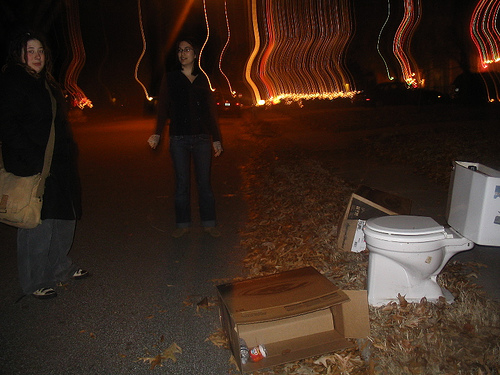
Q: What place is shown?
A: It is a roadside.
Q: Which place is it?
A: It is a roadside.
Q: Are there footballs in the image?
A: No, there are no footballs.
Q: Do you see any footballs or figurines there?
A: No, there are no footballs or figurines.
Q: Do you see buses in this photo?
A: No, there are no buses.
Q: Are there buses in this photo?
A: No, there are no buses.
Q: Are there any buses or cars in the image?
A: No, there are no buses or cars.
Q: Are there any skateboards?
A: No, there are no skateboards.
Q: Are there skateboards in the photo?
A: No, there are no skateboards.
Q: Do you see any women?
A: Yes, there is a woman.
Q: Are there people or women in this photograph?
A: Yes, there is a woman.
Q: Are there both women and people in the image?
A: Yes, there are both a woman and a person.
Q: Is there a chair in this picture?
A: No, there are no chairs.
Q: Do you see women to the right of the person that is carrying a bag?
A: Yes, there is a woman to the right of the person.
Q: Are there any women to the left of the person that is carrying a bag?
A: No, the woman is to the right of the person.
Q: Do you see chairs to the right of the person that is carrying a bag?
A: No, there is a woman to the right of the person.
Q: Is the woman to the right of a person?
A: Yes, the woman is to the right of a person.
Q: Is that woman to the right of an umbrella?
A: No, the woman is to the right of a person.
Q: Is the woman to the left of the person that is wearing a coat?
A: No, the woman is to the right of the person.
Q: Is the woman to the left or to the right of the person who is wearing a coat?
A: The woman is to the right of the person.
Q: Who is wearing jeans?
A: The woman is wearing jeans.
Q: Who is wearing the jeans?
A: The woman is wearing jeans.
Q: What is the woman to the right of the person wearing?
A: The woman is wearing jeans.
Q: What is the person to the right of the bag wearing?
A: The woman is wearing jeans.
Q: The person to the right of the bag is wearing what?
A: The woman is wearing jeans.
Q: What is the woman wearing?
A: The woman is wearing jeans.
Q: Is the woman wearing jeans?
A: Yes, the woman is wearing jeans.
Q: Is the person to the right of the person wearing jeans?
A: Yes, the woman is wearing jeans.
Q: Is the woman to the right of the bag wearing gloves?
A: No, the woman is wearing jeans.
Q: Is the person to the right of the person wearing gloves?
A: No, the woman is wearing jeans.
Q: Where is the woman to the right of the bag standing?
A: The woman is standing in the road.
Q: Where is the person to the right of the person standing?
A: The woman is standing in the road.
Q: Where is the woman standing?
A: The woman is standing in the road.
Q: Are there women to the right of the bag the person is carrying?
A: Yes, there is a woman to the right of the bag.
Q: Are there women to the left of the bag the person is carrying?
A: No, the woman is to the right of the bag.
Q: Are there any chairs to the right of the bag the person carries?
A: No, there is a woman to the right of the bag.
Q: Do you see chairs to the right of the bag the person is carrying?
A: No, there is a woman to the right of the bag.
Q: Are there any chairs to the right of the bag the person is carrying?
A: No, there is a woman to the right of the bag.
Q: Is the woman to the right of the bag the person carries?
A: Yes, the woman is to the right of the bag.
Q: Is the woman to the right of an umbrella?
A: No, the woman is to the right of the bag.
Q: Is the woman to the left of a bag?
A: No, the woman is to the right of a bag.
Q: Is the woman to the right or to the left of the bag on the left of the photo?
A: The woman is to the right of the bag.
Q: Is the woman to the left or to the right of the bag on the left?
A: The woman is to the right of the bag.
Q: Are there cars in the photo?
A: No, there are no cars.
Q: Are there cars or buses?
A: No, there are no cars or buses.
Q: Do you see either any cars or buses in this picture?
A: No, there are no cars or buses.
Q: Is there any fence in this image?
A: No, there are no fences.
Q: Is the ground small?
A: Yes, the ground is small.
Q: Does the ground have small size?
A: Yes, the ground is small.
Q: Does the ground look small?
A: Yes, the ground is small.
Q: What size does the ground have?
A: The ground has small size.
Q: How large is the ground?
A: The ground is small.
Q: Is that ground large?
A: No, the ground is small.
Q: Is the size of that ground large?
A: No, the ground is small.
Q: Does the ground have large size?
A: No, the ground is small.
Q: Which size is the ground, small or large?
A: The ground is small.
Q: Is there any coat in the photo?
A: Yes, there is a coat.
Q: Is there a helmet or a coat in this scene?
A: Yes, there is a coat.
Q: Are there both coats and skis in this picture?
A: No, there is a coat but no skis.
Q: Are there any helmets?
A: No, there are no helmets.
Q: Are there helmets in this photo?
A: No, there are no helmets.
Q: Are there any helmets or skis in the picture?
A: No, there are no helmets or skis.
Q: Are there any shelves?
A: No, there are no shelves.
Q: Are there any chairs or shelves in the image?
A: No, there are no shelves or chairs.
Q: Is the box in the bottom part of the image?
A: Yes, the box is in the bottom of the image.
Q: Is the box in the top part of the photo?
A: No, the box is in the bottom of the image.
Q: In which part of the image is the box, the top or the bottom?
A: The box is in the bottom of the image.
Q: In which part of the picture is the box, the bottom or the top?
A: The box is in the bottom of the image.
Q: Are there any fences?
A: No, there are no fences.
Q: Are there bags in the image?
A: Yes, there is a bag.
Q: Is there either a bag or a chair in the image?
A: Yes, there is a bag.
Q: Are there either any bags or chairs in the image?
A: Yes, there is a bag.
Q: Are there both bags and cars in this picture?
A: No, there is a bag but no cars.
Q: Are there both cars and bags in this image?
A: No, there is a bag but no cars.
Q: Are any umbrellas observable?
A: No, there are no umbrellas.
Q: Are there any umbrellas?
A: No, there are no umbrellas.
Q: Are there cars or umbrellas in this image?
A: No, there are no umbrellas or cars.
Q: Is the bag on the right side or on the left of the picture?
A: The bag is on the left of the image.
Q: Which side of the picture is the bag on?
A: The bag is on the left of the image.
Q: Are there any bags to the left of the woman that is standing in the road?
A: Yes, there is a bag to the left of the woman.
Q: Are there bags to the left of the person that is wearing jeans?
A: Yes, there is a bag to the left of the woman.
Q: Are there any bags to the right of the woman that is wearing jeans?
A: No, the bag is to the left of the woman.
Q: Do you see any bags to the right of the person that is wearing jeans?
A: No, the bag is to the left of the woman.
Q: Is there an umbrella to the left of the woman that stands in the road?
A: No, there is a bag to the left of the woman.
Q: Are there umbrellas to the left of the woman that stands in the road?
A: No, there is a bag to the left of the woman.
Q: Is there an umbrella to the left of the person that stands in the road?
A: No, there is a bag to the left of the woman.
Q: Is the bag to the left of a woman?
A: Yes, the bag is to the left of a woman.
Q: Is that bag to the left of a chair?
A: No, the bag is to the left of a woman.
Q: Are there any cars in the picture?
A: No, there are no cars.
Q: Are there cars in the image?
A: No, there are no cars.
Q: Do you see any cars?
A: No, there are no cars.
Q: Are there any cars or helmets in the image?
A: No, there are no cars or helmets.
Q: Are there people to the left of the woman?
A: Yes, there is a person to the left of the woman.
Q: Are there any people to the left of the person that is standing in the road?
A: Yes, there is a person to the left of the woman.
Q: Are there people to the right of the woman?
A: No, the person is to the left of the woman.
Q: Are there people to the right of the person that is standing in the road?
A: No, the person is to the left of the woman.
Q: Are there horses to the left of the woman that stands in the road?
A: No, there is a person to the left of the woman.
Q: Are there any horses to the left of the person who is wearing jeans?
A: No, there is a person to the left of the woman.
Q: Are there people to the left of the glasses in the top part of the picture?
A: Yes, there is a person to the left of the glasses.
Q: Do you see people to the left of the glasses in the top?
A: Yes, there is a person to the left of the glasses.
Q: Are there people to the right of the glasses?
A: No, the person is to the left of the glasses.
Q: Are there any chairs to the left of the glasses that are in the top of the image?
A: No, there is a person to the left of the glasses.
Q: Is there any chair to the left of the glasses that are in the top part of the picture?
A: No, there is a person to the left of the glasses.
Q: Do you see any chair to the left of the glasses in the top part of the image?
A: No, there is a person to the left of the glasses.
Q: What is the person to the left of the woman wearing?
A: The person is wearing a coat.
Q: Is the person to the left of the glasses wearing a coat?
A: Yes, the person is wearing a coat.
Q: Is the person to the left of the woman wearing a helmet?
A: No, the person is wearing a coat.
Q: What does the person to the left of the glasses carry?
A: The person carries a bag.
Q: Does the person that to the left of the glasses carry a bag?
A: Yes, the person carries a bag.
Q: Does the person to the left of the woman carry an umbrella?
A: No, the person carries a bag.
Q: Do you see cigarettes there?
A: No, there are no cigarettes.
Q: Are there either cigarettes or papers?
A: No, there are no cigarettes or papers.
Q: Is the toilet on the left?
A: No, the toilet is on the right of the image.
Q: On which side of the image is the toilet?
A: The toilet is on the right of the image.